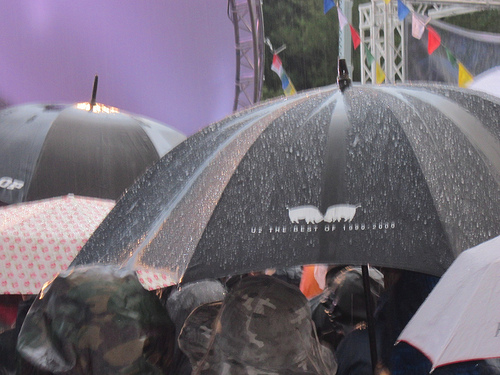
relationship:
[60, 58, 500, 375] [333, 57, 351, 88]
umbrella has point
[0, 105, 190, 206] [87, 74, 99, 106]
umbrella has point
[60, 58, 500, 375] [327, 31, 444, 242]
umbrella in rain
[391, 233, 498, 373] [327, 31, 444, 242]
umbrella in rain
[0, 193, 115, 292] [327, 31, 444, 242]
umbrella in rain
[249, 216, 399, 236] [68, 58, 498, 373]
lettering on umbrella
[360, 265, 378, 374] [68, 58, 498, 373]
handle on umbrella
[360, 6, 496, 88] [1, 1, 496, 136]
structure of stage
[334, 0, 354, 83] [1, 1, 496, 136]
structure of stage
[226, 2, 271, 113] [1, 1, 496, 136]
structure of stage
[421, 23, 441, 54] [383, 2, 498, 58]
red sheet on line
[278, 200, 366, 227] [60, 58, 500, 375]
image on umbrella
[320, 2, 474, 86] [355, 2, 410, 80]
flags hanging from beams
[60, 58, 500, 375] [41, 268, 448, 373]
umbrella held by people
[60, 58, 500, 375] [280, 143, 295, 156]
umbrella covered in drops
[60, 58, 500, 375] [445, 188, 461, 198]
umbrella covered in drops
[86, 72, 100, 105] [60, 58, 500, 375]
stick on umbrella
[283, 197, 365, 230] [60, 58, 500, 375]
trademark on umbrella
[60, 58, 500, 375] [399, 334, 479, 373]
umbrella with trim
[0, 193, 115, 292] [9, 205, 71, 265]
umbrella with pattern